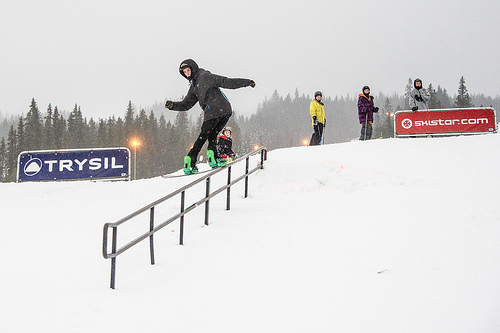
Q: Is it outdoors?
A: Yes, it is outdoors.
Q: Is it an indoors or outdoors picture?
A: It is outdoors.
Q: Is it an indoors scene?
A: No, it is outdoors.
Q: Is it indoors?
A: No, it is outdoors.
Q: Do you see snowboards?
A: Yes, there is a snowboard.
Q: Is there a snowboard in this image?
A: Yes, there is a snowboard.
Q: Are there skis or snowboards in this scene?
A: Yes, there is a snowboard.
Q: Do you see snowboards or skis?
A: Yes, there is a snowboard.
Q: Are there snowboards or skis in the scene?
A: Yes, there is a snowboard.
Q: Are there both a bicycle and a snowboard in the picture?
A: No, there is a snowboard but no bicycles.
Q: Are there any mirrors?
A: No, there are no mirrors.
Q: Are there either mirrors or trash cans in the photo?
A: No, there are no mirrors or trash cans.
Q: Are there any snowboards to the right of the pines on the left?
A: Yes, there is a snowboard to the right of the pine trees.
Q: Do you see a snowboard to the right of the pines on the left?
A: Yes, there is a snowboard to the right of the pine trees.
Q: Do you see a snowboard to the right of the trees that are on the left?
A: Yes, there is a snowboard to the right of the pine trees.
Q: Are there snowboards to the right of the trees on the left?
A: Yes, there is a snowboard to the right of the pine trees.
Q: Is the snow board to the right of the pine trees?
A: Yes, the snow board is to the right of the pine trees.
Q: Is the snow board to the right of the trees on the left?
A: Yes, the snow board is to the right of the pine trees.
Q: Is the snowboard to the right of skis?
A: No, the snowboard is to the right of the pine trees.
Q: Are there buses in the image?
A: No, there are no buses.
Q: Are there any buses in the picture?
A: No, there are no buses.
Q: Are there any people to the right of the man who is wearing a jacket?
A: Yes, there is a person to the right of the man.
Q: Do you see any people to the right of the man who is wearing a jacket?
A: Yes, there is a person to the right of the man.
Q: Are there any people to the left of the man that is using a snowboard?
A: No, the person is to the right of the man.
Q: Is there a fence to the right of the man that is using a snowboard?
A: No, there is a person to the right of the man.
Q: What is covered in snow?
A: The hill is covered in snow.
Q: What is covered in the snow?
A: The hill is covered in snow.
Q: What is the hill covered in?
A: The hill is covered in snow.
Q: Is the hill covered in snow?
A: Yes, the hill is covered in snow.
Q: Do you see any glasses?
A: No, there are no glasses.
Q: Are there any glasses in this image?
A: No, there are no glasses.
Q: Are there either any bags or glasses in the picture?
A: No, there are no glasses or bags.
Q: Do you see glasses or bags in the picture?
A: No, there are no glasses or bags.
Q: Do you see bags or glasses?
A: No, there are no glasses or bags.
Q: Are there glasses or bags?
A: No, there are no glasses or bags.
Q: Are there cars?
A: No, there are no cars.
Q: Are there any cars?
A: No, there are no cars.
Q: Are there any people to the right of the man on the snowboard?
A: Yes, there are people to the right of the man.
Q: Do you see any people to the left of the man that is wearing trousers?
A: No, the people are to the right of the man.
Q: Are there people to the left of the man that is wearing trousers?
A: No, the people are to the right of the man.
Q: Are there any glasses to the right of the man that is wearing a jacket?
A: No, there are people to the right of the man.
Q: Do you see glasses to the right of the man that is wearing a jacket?
A: No, there are people to the right of the man.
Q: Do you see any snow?
A: Yes, there is snow.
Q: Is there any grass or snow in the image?
A: Yes, there is snow.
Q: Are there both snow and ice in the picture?
A: No, there is snow but no ice.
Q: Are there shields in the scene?
A: No, there are no shields.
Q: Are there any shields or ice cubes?
A: No, there are no shields or ice cubes.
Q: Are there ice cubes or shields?
A: No, there are no shields or ice cubes.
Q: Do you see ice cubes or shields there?
A: No, there are no shields or ice cubes.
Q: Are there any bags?
A: No, there are no bags.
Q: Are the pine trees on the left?
A: Yes, the pine trees are on the left of the image.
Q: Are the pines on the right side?
A: No, the pines are on the left of the image.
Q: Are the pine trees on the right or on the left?
A: The pine trees are on the left of the image.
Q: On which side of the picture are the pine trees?
A: The pine trees are on the left of the image.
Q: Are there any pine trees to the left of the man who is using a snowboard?
A: Yes, there are pine trees to the left of the man.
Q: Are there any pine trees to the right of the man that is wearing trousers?
A: No, the pine trees are to the left of the man.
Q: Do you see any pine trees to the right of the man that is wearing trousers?
A: No, the pine trees are to the left of the man.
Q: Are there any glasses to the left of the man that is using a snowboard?
A: No, there are pine trees to the left of the man.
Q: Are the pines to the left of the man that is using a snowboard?
A: Yes, the pines are to the left of the man.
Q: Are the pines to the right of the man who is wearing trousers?
A: No, the pines are to the left of the man.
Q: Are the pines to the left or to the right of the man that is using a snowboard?
A: The pines are to the left of the man.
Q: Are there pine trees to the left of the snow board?
A: Yes, there are pine trees to the left of the snow board.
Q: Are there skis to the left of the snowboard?
A: No, there are pine trees to the left of the snowboard.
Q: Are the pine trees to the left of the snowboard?
A: Yes, the pine trees are to the left of the snowboard.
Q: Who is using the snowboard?
A: The man is using the snowboard.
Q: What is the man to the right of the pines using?
A: The man is using a snow board.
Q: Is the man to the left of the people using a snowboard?
A: Yes, the man is using a snowboard.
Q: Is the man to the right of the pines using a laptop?
A: No, the man is using a snowboard.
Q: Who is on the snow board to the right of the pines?
A: The man is on the snowboard.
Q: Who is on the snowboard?
A: The man is on the snowboard.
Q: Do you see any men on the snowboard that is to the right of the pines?
A: Yes, there is a man on the snowboard.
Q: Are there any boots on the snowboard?
A: No, there is a man on the snowboard.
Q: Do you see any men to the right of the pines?
A: Yes, there is a man to the right of the pines.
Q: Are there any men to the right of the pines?
A: Yes, there is a man to the right of the pines.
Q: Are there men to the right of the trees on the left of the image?
A: Yes, there is a man to the right of the pines.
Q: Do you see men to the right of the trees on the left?
A: Yes, there is a man to the right of the pines.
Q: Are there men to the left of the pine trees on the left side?
A: No, the man is to the right of the pines.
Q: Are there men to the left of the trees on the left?
A: No, the man is to the right of the pines.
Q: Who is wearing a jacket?
A: The man is wearing a jacket.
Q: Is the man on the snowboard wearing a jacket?
A: Yes, the man is wearing a jacket.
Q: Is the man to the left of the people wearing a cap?
A: No, the man is wearing a jacket.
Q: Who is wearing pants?
A: The man is wearing pants.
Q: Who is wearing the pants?
A: The man is wearing pants.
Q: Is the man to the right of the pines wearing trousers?
A: Yes, the man is wearing trousers.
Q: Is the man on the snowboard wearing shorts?
A: No, the man is wearing trousers.